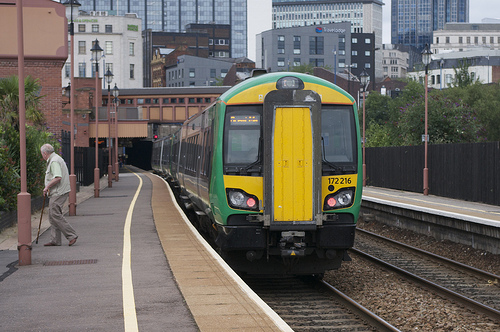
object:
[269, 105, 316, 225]
panel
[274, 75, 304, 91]
sign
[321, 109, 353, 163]
window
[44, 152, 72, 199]
shirt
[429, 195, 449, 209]
ground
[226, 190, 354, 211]
headlights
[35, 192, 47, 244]
cane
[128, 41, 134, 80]
window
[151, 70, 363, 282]
train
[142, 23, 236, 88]
buildings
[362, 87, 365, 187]
pole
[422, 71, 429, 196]
pole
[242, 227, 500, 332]
track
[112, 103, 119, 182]
metal pole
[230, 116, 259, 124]
lights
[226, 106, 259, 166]
window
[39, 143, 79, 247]
man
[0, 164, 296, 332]
platform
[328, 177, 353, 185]
numbers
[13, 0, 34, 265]
lamps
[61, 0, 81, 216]
lamps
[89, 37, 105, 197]
lamps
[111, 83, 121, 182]
lamps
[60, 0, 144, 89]
building